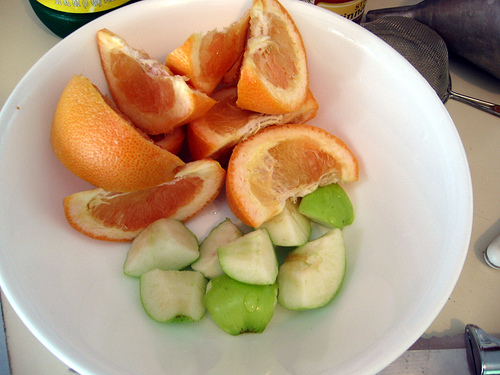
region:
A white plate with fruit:
[3, 40, 448, 370]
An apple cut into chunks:
[129, 241, 337, 321]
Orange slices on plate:
[70, 57, 376, 209]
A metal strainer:
[395, 26, 472, 99]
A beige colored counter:
[470, 125, 497, 212]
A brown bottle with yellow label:
[16, 0, 99, 27]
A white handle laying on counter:
[481, 225, 496, 280]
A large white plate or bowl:
[375, 79, 482, 274]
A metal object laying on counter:
[463, 319, 499, 374]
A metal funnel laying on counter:
[376, 6, 498, 66]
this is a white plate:
[4, 0, 475, 374]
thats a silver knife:
[374, 322, 497, 374]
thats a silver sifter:
[356, 12, 497, 115]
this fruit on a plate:
[49, 0, 362, 335]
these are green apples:
[120, 182, 367, 336]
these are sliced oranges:
[46, 0, 361, 244]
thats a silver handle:
[484, 232, 497, 271]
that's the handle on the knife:
[462, 321, 498, 373]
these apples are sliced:
[121, 183, 366, 337]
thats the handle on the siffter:
[451, 83, 498, 117]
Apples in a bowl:
[110, 180, 356, 335]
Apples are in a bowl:
[120, 175, 351, 336]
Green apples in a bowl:
[119, 177, 355, 335]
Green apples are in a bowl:
[123, 179, 355, 335]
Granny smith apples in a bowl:
[122, 179, 354, 339]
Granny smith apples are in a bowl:
[118, 178, 349, 334]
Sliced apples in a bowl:
[115, 180, 350, 335]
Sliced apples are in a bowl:
[115, 180, 350, 335]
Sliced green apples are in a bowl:
[120, 176, 355, 337]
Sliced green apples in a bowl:
[121, 171, 356, 335]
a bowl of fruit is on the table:
[35, 37, 407, 327]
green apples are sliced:
[155, 190, 435, 318]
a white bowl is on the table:
[16, 46, 469, 366]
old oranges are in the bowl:
[60, 28, 346, 166]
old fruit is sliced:
[65, 54, 385, 286]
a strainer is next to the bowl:
[354, 8, 499, 100]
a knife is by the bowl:
[380, 321, 460, 370]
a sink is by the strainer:
[392, 3, 484, 63]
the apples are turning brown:
[119, 219, 494, 351]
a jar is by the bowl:
[28, 4, 118, 39]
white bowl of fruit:
[7, 3, 472, 372]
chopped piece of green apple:
[224, 226, 278, 288]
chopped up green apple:
[120, 182, 359, 337]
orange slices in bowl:
[43, 5, 358, 235]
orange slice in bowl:
[226, 123, 357, 228]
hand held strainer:
[362, 15, 499, 122]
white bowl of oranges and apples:
[8, 2, 470, 374]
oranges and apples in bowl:
[45, 3, 352, 338]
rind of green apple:
[204, 275, 276, 337]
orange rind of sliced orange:
[50, 75, 185, 196]